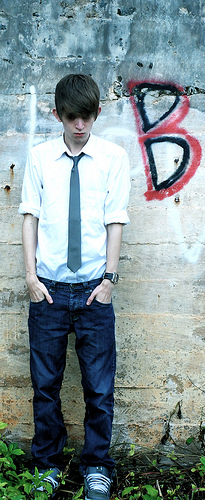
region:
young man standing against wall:
[16, 73, 129, 499]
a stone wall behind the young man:
[0, 0, 203, 468]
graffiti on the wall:
[126, 78, 201, 201]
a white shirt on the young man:
[18, 130, 131, 283]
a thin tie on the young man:
[63, 150, 86, 272]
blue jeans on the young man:
[27, 274, 113, 469]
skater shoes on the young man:
[26, 465, 111, 498]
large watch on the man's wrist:
[103, 271, 118, 285]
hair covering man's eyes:
[54, 73, 99, 123]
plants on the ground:
[0, 422, 204, 498]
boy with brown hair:
[17, 71, 123, 498]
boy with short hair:
[14, 70, 133, 499]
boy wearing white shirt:
[14, 68, 137, 499]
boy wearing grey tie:
[17, 71, 122, 498]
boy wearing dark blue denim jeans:
[18, 66, 120, 499]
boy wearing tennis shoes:
[17, 63, 126, 498]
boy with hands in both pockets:
[20, 67, 125, 499]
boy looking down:
[22, 71, 122, 499]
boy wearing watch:
[18, 66, 121, 499]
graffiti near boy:
[10, 57, 203, 499]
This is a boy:
[10, 64, 147, 498]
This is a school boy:
[13, 62, 143, 499]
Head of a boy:
[33, 61, 110, 157]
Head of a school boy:
[42, 63, 113, 163]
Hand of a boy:
[89, 145, 135, 316]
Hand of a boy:
[12, 147, 52, 313]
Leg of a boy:
[71, 304, 115, 496]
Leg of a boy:
[25, 298, 74, 497]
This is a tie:
[55, 143, 96, 281]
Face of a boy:
[65, 106, 93, 146]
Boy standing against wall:
[7, 63, 112, 295]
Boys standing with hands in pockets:
[13, 76, 128, 327]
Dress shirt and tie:
[4, 131, 126, 267]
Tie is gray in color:
[61, 182, 89, 275]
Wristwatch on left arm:
[95, 258, 121, 289]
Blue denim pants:
[13, 273, 111, 404]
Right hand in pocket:
[6, 238, 53, 316]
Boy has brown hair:
[49, 69, 118, 147]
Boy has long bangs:
[52, 95, 99, 162]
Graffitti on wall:
[118, 68, 191, 187]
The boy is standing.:
[14, 76, 139, 496]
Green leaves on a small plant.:
[0, 430, 56, 497]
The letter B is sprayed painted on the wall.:
[120, 71, 199, 196]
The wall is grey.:
[6, 26, 178, 57]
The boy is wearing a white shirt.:
[13, 130, 120, 290]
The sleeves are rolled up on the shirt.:
[14, 196, 129, 227]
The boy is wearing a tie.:
[59, 149, 85, 274]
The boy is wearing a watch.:
[101, 267, 120, 281]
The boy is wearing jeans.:
[23, 271, 115, 465]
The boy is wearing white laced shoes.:
[32, 463, 115, 498]